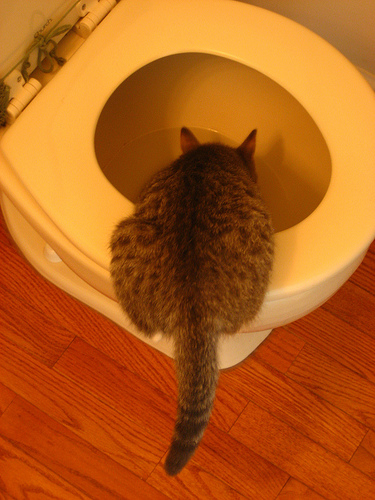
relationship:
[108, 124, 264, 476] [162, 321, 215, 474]
cat has tail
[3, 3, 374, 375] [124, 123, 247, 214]
toilet has water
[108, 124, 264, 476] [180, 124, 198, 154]
cat has ear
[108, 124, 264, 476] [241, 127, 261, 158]
cat has ear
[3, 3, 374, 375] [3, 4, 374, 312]
toilet has seat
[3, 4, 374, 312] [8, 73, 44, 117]
seat has hinge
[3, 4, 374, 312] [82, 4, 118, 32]
seat has hinge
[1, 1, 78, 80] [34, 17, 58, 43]
toilet seat cover has word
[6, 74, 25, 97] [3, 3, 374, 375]
screw cap on side of toilet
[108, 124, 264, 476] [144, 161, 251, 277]
cat has back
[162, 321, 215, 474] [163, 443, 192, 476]
tail has tip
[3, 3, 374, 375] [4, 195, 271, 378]
toilet has base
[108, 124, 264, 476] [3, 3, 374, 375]
cat drinking from toilet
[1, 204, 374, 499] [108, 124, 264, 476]
floor below cat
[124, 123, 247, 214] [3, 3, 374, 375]
water inside toilet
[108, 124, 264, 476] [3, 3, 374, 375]
cat standing on toilet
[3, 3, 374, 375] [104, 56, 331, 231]
toilet has bowl